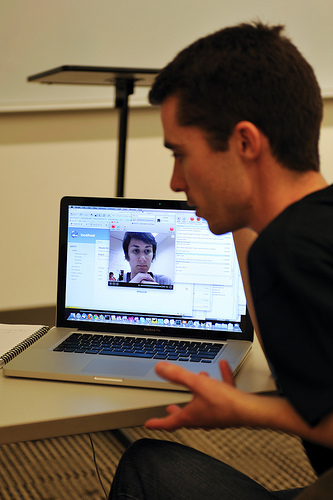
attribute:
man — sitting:
[129, 56, 332, 385]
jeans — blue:
[106, 438, 273, 500]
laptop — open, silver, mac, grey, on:
[7, 192, 259, 397]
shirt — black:
[244, 183, 330, 426]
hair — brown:
[156, 29, 322, 169]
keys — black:
[55, 332, 224, 367]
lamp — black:
[27, 60, 176, 198]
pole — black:
[115, 97, 127, 196]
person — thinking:
[125, 36, 332, 499]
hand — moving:
[147, 359, 252, 437]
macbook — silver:
[7, 192, 256, 389]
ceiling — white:
[9, 3, 330, 57]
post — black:
[106, 97, 135, 199]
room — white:
[3, 3, 332, 491]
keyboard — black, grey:
[48, 321, 230, 382]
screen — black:
[76, 208, 239, 316]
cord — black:
[85, 431, 98, 499]